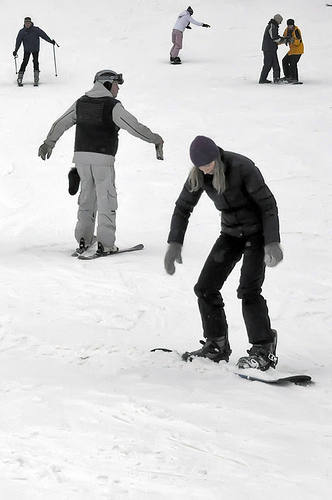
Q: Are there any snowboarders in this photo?
A: Yes, there is a snowboarder.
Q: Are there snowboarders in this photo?
A: Yes, there is a snowboarder.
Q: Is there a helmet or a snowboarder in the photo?
A: Yes, there is a snowboarder.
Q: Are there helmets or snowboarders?
A: Yes, there is a snowboarder.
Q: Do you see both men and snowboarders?
A: Yes, there are both a snowboarder and a man.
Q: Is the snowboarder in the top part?
A: Yes, the snowboarder is in the top of the image.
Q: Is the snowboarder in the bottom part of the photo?
A: No, the snowboarder is in the top of the image.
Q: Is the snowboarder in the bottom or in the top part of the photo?
A: The snowboarder is in the top of the image.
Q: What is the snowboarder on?
A: The snowboarder is on the snowboard.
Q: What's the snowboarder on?
A: The snowboarder is on the snowboard.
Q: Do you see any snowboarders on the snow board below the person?
A: Yes, there is a snowboarder on the snowboard.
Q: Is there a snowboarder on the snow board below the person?
A: Yes, there is a snowboarder on the snowboard.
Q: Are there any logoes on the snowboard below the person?
A: No, there is a snowboarder on the snowboard.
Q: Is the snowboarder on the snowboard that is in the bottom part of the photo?
A: Yes, the snowboarder is on the snowboard.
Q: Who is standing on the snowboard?
A: The snowboarder is standing on the snowboard.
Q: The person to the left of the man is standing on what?
A: The snowboarder is standing on the snowboard.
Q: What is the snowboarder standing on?
A: The snowboarder is standing on the snowboard.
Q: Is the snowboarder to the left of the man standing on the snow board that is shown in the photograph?
A: Yes, the snowboarder is standing on the snow board.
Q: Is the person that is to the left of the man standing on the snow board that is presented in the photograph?
A: Yes, the snowboarder is standing on the snow board.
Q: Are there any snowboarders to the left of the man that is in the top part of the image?
A: Yes, there is a snowboarder to the left of the man.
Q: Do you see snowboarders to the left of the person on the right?
A: Yes, there is a snowboarder to the left of the man.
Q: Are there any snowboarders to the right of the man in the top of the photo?
A: No, the snowboarder is to the left of the man.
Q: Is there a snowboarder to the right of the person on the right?
A: No, the snowboarder is to the left of the man.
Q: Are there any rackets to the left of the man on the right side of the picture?
A: No, there is a snowboarder to the left of the man.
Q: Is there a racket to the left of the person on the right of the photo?
A: No, there is a snowboarder to the left of the man.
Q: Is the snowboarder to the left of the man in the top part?
A: Yes, the snowboarder is to the left of the man.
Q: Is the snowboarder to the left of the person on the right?
A: Yes, the snowboarder is to the left of the man.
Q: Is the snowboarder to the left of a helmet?
A: No, the snowboarder is to the left of the man.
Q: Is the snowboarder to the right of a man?
A: No, the snowboarder is to the left of a man.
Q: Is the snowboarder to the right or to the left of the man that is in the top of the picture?
A: The snowboarder is to the left of the man.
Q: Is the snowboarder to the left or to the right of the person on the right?
A: The snowboarder is to the left of the man.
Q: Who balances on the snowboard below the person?
A: The snowboarder balances on the snowboard.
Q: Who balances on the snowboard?
A: The snowboarder balances on the snowboard.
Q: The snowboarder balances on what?
A: The snowboarder balances on the snowboard.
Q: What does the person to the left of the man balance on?
A: The snowboarder balances on the snowboard.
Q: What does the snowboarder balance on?
A: The snowboarder balances on the snowboard.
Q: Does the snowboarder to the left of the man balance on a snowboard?
A: Yes, the snowboarder balances on a snowboard.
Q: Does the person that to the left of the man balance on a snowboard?
A: Yes, the snowboarder balances on a snowboard.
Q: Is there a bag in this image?
A: No, there are no bags.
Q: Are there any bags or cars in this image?
A: No, there are no bags or cars.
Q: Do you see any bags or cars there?
A: No, there are no bags or cars.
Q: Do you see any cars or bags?
A: No, there are no bags or cars.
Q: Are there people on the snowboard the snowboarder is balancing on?
A: Yes, there is a person on the snowboard.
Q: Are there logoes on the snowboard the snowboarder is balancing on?
A: No, there is a person on the snowboard.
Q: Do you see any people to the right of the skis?
A: Yes, there is a person to the right of the skis.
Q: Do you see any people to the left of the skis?
A: No, the person is to the right of the skis.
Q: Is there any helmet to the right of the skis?
A: No, there is a person to the right of the skis.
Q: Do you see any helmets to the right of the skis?
A: No, there is a person to the right of the skis.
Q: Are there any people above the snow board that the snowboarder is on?
A: Yes, there is a person above the snowboard.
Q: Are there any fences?
A: No, there are no fences.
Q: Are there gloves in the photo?
A: Yes, there are gloves.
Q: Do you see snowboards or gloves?
A: Yes, there are gloves.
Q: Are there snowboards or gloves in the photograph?
A: Yes, there are gloves.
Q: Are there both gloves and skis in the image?
A: Yes, there are both gloves and a ski.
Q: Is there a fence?
A: No, there are no fences.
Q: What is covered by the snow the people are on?
A: The ground is covered by the snow.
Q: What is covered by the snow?
A: The ground is covered by the snow.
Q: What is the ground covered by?
A: The ground is covered by the snow.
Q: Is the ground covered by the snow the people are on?
A: Yes, the ground is covered by the snow.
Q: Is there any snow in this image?
A: Yes, there is snow.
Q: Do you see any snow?
A: Yes, there is snow.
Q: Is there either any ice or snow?
A: Yes, there is snow.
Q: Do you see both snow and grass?
A: No, there is snow but no grass.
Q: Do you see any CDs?
A: No, there are no cds.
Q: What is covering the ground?
A: The snow is covering the ground.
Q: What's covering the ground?
A: The snow is covering the ground.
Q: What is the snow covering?
A: The snow is covering the ground.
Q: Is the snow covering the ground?
A: Yes, the snow is covering the ground.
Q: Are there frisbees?
A: No, there are no frisbees.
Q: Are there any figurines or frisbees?
A: No, there are no frisbees or figurines.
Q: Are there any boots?
A: Yes, there are boots.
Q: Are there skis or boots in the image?
A: Yes, there are boots.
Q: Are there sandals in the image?
A: No, there are no sandals.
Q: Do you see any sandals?
A: No, there are no sandals.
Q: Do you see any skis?
A: Yes, there are skis.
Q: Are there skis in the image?
A: Yes, there are skis.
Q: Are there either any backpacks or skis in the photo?
A: Yes, there are skis.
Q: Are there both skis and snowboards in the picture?
A: Yes, there are both skis and a snowboard.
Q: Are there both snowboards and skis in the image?
A: Yes, there are both skis and a snowboard.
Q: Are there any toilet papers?
A: No, there are no toilet papers.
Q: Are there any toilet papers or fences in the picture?
A: No, there are no toilet papers or fences.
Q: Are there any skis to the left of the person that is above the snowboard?
A: Yes, there are skis to the left of the person.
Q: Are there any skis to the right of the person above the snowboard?
A: No, the skis are to the left of the person.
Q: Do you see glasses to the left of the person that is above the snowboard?
A: No, there are skis to the left of the person.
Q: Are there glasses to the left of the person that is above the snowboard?
A: No, there are skis to the left of the person.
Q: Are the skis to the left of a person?
A: Yes, the skis are to the left of a person.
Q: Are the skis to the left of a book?
A: No, the skis are to the left of a person.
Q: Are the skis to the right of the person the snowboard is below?
A: No, the skis are to the left of the person.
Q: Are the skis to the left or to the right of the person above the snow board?
A: The skis are to the left of the person.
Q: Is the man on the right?
A: Yes, the man is on the right of the image.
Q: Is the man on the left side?
A: No, the man is on the right of the image.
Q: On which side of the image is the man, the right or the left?
A: The man is on the right of the image.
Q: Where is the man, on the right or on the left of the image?
A: The man is on the right of the image.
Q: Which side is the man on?
A: The man is on the right of the image.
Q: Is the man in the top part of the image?
A: Yes, the man is in the top of the image.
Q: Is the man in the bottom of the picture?
A: No, the man is in the top of the image.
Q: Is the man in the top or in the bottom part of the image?
A: The man is in the top of the image.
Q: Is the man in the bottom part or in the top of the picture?
A: The man is in the top of the image.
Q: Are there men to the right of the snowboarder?
A: Yes, there is a man to the right of the snowboarder.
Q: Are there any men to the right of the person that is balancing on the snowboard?
A: Yes, there is a man to the right of the snowboarder.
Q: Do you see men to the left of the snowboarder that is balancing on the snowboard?
A: No, the man is to the right of the snowboarder.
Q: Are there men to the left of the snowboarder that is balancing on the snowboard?
A: No, the man is to the right of the snowboarder.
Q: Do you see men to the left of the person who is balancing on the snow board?
A: No, the man is to the right of the snowboarder.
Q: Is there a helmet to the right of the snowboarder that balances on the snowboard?
A: No, there is a man to the right of the snowboarder.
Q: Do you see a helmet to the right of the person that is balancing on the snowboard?
A: No, there is a man to the right of the snowboarder.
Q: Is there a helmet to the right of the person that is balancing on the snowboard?
A: No, there is a man to the right of the snowboarder.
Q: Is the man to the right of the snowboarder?
A: Yes, the man is to the right of the snowboarder.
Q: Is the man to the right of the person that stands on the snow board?
A: Yes, the man is to the right of the snowboarder.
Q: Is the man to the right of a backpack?
A: No, the man is to the right of the snowboarder.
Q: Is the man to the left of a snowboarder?
A: No, the man is to the right of a snowboarder.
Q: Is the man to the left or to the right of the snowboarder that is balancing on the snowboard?
A: The man is to the right of the snowboarder.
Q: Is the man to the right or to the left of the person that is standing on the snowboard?
A: The man is to the right of the snowboarder.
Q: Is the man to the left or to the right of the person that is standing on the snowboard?
A: The man is to the right of the snowboarder.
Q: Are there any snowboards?
A: Yes, there is a snowboard.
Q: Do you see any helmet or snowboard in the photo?
A: Yes, there is a snowboard.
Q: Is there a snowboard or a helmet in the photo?
A: Yes, there is a snowboard.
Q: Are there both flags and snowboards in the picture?
A: No, there is a snowboard but no flags.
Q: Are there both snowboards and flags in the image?
A: No, there is a snowboard but no flags.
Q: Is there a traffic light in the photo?
A: No, there are no traffic lights.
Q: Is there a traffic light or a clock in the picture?
A: No, there are no traffic lights or clocks.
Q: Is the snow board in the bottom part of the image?
A: Yes, the snow board is in the bottom of the image.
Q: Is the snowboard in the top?
A: No, the snowboard is in the bottom of the image.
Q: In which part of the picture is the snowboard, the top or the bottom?
A: The snowboard is in the bottom of the image.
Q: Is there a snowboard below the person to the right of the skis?
A: Yes, there is a snowboard below the person.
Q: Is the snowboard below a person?
A: Yes, the snowboard is below a person.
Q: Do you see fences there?
A: No, there are no fences.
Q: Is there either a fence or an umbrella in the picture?
A: No, there are no fences or umbrellas.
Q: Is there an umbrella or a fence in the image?
A: No, there are no fences or umbrellas.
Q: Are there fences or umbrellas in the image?
A: No, there are no fences or umbrellas.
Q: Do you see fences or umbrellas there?
A: No, there are no fences or umbrellas.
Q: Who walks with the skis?
A: The people walk with the skis.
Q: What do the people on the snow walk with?
A: The people walk with skis.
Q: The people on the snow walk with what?
A: The people walk with skis.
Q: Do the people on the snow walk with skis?
A: Yes, the people walk with skis.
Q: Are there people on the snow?
A: Yes, there are people on the snow.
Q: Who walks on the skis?
A: The people walk on the skis.